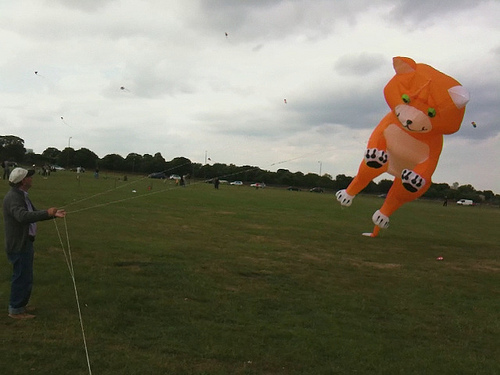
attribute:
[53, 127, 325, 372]
string — white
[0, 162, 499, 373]
grass — short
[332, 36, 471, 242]
balloon — orange, large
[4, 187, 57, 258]
jacket — brown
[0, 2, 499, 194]
sky — overcast, gray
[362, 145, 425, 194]
paws — black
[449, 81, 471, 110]
his ear — white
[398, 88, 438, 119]
eyes — green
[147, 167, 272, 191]
cars — parallel parked